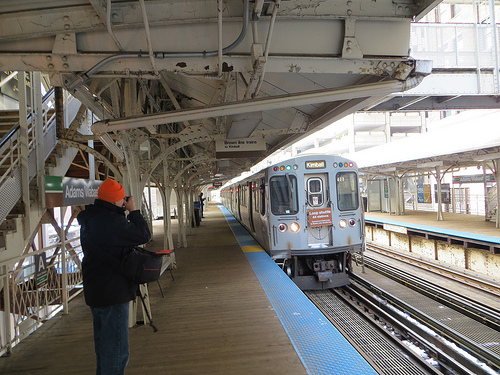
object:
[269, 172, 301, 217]
window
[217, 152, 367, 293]
train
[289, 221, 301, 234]
headlight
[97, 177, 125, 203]
beanie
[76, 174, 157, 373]
person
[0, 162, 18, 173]
stairs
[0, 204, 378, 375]
platform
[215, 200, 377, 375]
blue line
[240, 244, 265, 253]
paint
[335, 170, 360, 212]
window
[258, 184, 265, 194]
head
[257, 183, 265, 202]
person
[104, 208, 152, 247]
arm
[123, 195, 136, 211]
hand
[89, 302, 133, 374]
jeans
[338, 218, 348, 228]
headlight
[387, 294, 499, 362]
tracks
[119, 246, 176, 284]
bag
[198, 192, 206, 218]
person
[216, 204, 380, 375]
edge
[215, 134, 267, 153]
sign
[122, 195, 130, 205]
camera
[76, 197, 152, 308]
black jacket